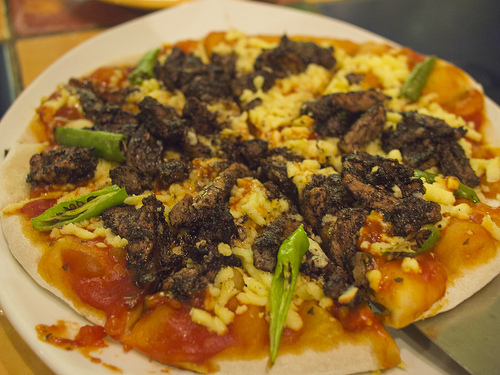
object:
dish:
[3, 2, 495, 371]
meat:
[306, 204, 372, 293]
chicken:
[104, 90, 195, 194]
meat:
[346, 145, 394, 192]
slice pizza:
[283, 163, 424, 230]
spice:
[377, 192, 457, 267]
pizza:
[0, 28, 499, 373]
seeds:
[75, 201, 83, 207]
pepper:
[32, 184, 125, 231]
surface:
[421, 299, 498, 361]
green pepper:
[259, 219, 310, 361]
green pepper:
[128, 43, 163, 83]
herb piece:
[391, 262, 408, 286]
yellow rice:
[187, 266, 247, 342]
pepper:
[403, 52, 438, 103]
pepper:
[411, 169, 478, 203]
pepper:
[414, 225, 441, 252]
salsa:
[154, 306, 219, 346]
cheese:
[204, 241, 269, 308]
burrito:
[12, 40, 499, 352]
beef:
[28, 145, 102, 184]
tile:
[12, 25, 113, 95]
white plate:
[0, 0, 497, 374]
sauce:
[33, 319, 125, 374]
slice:
[206, 17, 356, 177]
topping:
[116, 86, 394, 306]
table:
[0, 11, 498, 375]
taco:
[26, 90, 466, 347]